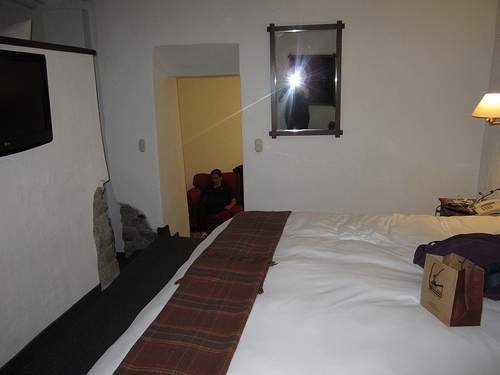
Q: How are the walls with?
A: Brick.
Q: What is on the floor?
A: Bed.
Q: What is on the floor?
A: Door.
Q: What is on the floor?
A: Comforter.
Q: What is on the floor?
A: Mirror.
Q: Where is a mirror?
A: Wall next to bed.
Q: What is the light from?
A: A flash.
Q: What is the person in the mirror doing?
A: Taking a selfie.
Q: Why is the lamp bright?
A: The light is on.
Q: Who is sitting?
A: A man.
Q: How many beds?
A: One.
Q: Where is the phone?
A: On the bed stand.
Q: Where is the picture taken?
A: In a bedroom.